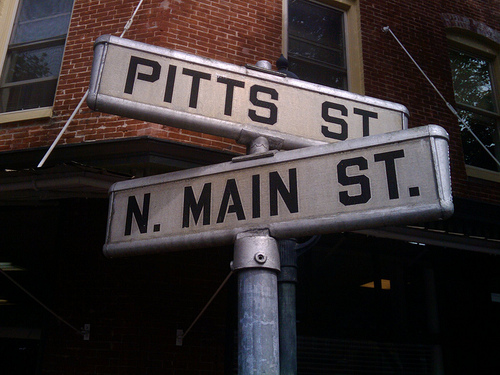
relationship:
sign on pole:
[101, 123, 457, 258] [233, 228, 282, 374]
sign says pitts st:
[87, 34, 409, 155] [125, 55, 378, 141]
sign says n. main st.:
[101, 123, 457, 258] [126, 150, 420, 237]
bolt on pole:
[255, 253, 267, 264] [233, 228, 282, 374]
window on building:
[282, 1, 349, 94] [0, 0, 499, 203]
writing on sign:
[125, 150, 422, 236] [101, 123, 457, 258]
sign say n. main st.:
[101, 123, 457, 258] [126, 150, 420, 237]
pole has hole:
[233, 228, 282, 374] [254, 252, 266, 264]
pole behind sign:
[246, 135, 271, 157] [101, 123, 457, 258]